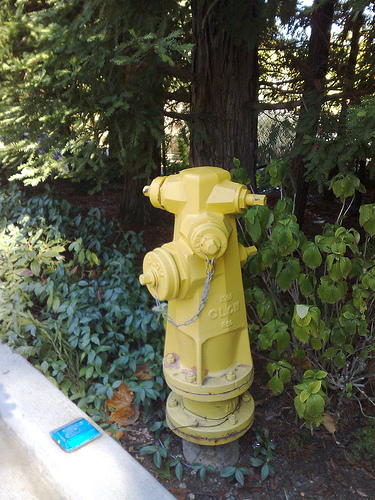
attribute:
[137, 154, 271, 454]
hydrant — yellow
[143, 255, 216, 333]
chain — silver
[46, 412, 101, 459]
reflector — blue, light blue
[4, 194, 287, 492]
leaves — dead, green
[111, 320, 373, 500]
dirt — brown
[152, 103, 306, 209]
fence — chain link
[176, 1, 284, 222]
trees — brown, wooden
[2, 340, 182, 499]
curb — concrete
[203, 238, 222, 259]
valve — circular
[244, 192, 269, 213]
valve — upper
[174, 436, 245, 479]
base — grey